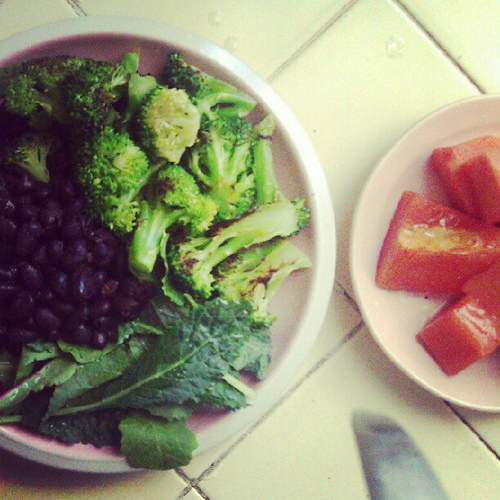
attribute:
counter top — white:
[2, 4, 494, 498]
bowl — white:
[0, 16, 365, 491]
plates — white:
[11, 17, 356, 461]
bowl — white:
[3, 15, 339, 475]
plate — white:
[349, 90, 494, 432]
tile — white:
[272, 0, 481, 329]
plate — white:
[9, 16, 337, 474]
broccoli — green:
[3, 48, 315, 325]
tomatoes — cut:
[371, 131, 498, 374]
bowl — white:
[6, 18, 343, 406]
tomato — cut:
[379, 187, 489, 295]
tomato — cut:
[430, 130, 497, 215]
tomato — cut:
[416, 286, 498, 375]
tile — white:
[196, 317, 499, 499]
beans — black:
[14, 182, 121, 362]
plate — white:
[11, 36, 337, 427]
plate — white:
[346, 95, 498, 410]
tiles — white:
[0, 1, 499, 498]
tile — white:
[270, 8, 471, 91]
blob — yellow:
[399, 219, 474, 252]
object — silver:
[353, 407, 445, 497]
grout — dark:
[399, 0, 488, 93]